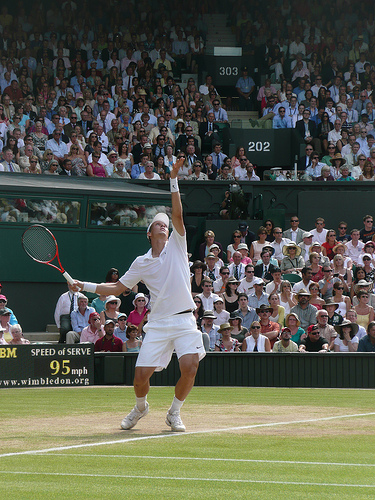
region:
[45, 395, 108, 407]
green grass court surface.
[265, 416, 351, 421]
white chalk boundary line.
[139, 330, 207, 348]
white tennis shorts.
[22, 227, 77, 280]
tennis racquet in player's hand.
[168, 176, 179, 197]
white embroidered wrist band.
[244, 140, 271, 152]
white numbers on green background.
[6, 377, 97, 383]
website address on green background.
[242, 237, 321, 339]
spectators watching the match.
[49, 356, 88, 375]
speed of serve.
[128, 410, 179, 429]
pair of white tennis shoes.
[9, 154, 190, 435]
this is a tennis player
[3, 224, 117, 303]
the right hand is holding a racket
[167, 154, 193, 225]
the left hand is lifted on air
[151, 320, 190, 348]
the payer has white shorts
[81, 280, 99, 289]
the player has white wrist band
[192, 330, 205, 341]
a ball is on the players pocket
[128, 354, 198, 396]
the knees are bent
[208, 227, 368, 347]
these3 are spectators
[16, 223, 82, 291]
the racket is red in color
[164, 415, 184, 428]
the shoes are white in color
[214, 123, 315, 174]
section 202 of the stadium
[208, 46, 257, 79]
section 303 of the stadium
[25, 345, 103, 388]
sign that shows speed of the serve at a tennis match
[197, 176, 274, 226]
camera person video recording the tennis match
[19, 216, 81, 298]
Red and white tennis racket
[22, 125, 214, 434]
tennis player going to serve the ball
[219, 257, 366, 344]
people watching the tennis match in stands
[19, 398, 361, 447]
worn turf from the player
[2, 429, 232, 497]
white painted lines defining the court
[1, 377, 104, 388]
advertisement of Wimbledon website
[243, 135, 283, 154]
white numbers on a black background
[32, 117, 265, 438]
a man hitting a tennis ball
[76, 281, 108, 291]
a white wristband on an arm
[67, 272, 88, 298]
a hand grasping a red tennis racket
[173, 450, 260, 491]
white lines marking the tennis court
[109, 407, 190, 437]
white sneakers covering feet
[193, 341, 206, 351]
a logo on white shorts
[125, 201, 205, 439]
a man wearing a white tennis uniform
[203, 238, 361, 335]
a crowd watching a tennis game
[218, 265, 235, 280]
a man wearing sunglasses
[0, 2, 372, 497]
spectators watching a tennis activity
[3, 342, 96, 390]
sign announcing speed of tennis serves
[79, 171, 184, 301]
large white bands around man's wrists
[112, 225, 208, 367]
man is wearing a white outfit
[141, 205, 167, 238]
man is wearing a white hat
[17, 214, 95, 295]
man holding tennis racket with his right hand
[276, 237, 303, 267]
woman wearing a large floppy hat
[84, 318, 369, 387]
low wall in front of spectators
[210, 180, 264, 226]
person sitting behind a large camera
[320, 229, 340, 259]
woman wearing a red top